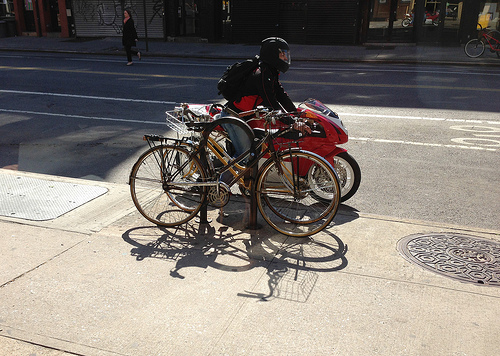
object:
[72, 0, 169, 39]
shutter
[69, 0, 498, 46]
shop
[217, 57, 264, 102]
backpack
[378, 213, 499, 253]
pothole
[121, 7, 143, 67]
woman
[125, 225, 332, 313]
shadow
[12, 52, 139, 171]
road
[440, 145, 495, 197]
ground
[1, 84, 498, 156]
lines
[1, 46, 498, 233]
street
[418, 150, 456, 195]
ground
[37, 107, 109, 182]
road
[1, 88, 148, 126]
lines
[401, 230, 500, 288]
manhole cover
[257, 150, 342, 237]
tire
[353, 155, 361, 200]
rubber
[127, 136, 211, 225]
tire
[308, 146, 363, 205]
tire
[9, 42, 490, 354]
road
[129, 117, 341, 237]
bicycle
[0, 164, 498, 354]
sidewalk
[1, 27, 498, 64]
sidewalk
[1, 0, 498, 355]
city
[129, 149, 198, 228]
spikes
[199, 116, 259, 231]
pole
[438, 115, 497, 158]
letters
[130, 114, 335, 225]
bicycle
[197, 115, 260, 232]
u pole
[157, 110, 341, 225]
yellow bike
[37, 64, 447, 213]
road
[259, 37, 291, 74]
helmet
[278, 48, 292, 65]
visor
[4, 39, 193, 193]
street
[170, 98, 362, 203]
motorcycle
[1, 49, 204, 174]
street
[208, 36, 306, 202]
person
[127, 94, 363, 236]
bikes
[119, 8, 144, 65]
pedestrian